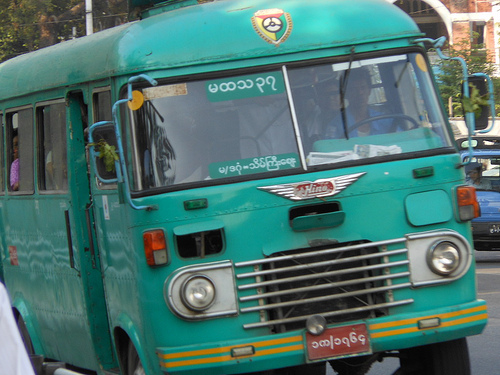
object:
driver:
[324, 66, 404, 138]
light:
[184, 198, 209, 211]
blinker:
[143, 229, 170, 266]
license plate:
[306, 323, 370, 360]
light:
[231, 345, 256, 357]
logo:
[250, 9, 292, 45]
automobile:
[0, 0, 488, 375]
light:
[306, 315, 327, 337]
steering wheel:
[340, 114, 419, 139]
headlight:
[427, 239, 462, 276]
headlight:
[179, 274, 215, 312]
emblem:
[256, 172, 367, 202]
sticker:
[208, 153, 302, 180]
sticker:
[205, 71, 287, 103]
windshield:
[119, 52, 452, 192]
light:
[458, 185, 482, 221]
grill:
[233, 237, 413, 330]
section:
[91, 133, 328, 363]